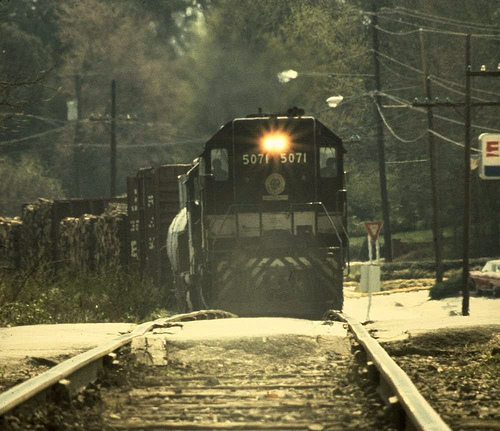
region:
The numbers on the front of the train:
[241, 148, 312, 172]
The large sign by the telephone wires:
[472, 126, 499, 185]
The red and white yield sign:
[362, 217, 383, 247]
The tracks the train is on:
[2, 310, 455, 430]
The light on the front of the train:
[258, 126, 290, 153]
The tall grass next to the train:
[2, 256, 177, 333]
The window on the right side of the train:
[319, 143, 340, 181]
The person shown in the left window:
[211, 154, 227, 179]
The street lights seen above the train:
[274, 59, 354, 113]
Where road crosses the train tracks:
[120, 312, 377, 337]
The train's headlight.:
[241, 116, 307, 167]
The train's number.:
[235, 145, 315, 165]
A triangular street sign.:
[355, 205, 385, 245]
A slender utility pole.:
[400, 35, 485, 315]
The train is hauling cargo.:
[2, 97, 343, 297]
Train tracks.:
[55, 285, 407, 406]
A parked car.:
[460, 250, 495, 305]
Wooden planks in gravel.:
[132, 370, 333, 425]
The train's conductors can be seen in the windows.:
[205, 145, 335, 182]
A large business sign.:
[455, 121, 498, 188]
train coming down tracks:
[195, 121, 377, 377]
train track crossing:
[133, 301, 484, 428]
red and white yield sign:
[359, 210, 399, 265]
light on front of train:
[238, 116, 313, 178]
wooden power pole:
[408, 13, 498, 307]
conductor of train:
[201, 138, 234, 193]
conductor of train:
[305, 135, 350, 193]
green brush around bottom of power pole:
[434, 263, 476, 307]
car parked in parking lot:
[471, 251, 498, 295]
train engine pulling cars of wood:
[4, 108, 361, 327]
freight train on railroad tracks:
[19, 60, 473, 410]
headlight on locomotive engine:
[247, 108, 303, 170]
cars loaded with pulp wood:
[10, 197, 149, 289]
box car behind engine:
[119, 155, 184, 296]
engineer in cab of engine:
[205, 143, 238, 193]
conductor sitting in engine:
[315, 138, 347, 188]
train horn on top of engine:
[275, 98, 313, 124]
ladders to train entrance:
[203, 189, 348, 289]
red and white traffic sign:
[360, 213, 393, 295]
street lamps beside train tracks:
[266, 44, 419, 224]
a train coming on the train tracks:
[0, 87, 423, 397]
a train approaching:
[14, 89, 403, 354]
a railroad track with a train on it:
[76, 97, 401, 424]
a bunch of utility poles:
[344, 11, 499, 336]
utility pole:
[73, 61, 155, 235]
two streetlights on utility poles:
[266, 34, 436, 160]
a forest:
[24, 11, 498, 236]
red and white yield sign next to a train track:
[312, 204, 404, 346]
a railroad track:
[12, 220, 437, 426]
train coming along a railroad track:
[17, 76, 472, 420]